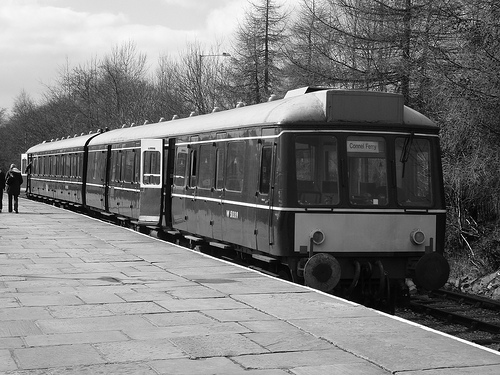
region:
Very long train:
[18, 86, 468, 297]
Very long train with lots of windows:
[15, 88, 465, 295]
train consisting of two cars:
[19, 77, 449, 300]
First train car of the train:
[84, 61, 463, 330]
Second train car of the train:
[16, 91, 99, 221]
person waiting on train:
[4, 148, 22, 219]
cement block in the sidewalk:
[171, 327, 266, 360]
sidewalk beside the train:
[0, 182, 497, 372]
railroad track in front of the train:
[374, 249, 496, 347]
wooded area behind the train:
[0, 59, 492, 133]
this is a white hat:
[6, 163, 23, 175]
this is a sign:
[337, 132, 384, 154]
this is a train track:
[396, 260, 498, 355]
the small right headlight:
[307, 225, 332, 244]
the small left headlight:
[396, 216, 443, 256]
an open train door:
[137, 120, 166, 233]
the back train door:
[12, 151, 38, 196]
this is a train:
[15, 96, 446, 314]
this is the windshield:
[283, 123, 444, 216]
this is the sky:
[15, 69, 50, 98]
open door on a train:
[139, 129, 163, 228]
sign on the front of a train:
[336, 130, 386, 164]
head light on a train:
[307, 221, 332, 248]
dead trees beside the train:
[65, 58, 225, 110]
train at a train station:
[10, 75, 472, 307]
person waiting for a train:
[4, 156, 29, 221]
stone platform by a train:
[14, 219, 181, 364]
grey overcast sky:
[14, 46, 53, 77]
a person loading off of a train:
[22, 143, 39, 188]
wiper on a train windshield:
[398, 104, 420, 181]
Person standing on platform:
[3, 148, 84, 235]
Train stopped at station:
[18, 104, 457, 296]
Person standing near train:
[2, 103, 362, 283]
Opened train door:
[129, 114, 199, 244]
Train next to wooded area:
[29, 34, 491, 317]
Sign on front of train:
[291, 89, 442, 281]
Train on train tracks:
[274, 57, 496, 349]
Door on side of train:
[131, 133, 163, 226]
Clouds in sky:
[22, 6, 247, 46]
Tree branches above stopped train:
[290, 8, 460, 309]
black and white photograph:
[6, 0, 499, 368]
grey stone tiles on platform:
[2, 197, 495, 372]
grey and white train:
[10, 74, 467, 303]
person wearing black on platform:
[1, 160, 25, 215]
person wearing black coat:
[3, 160, 31, 216]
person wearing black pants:
[5, 158, 24, 218]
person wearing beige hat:
[7, 162, 25, 212]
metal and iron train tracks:
[381, 279, 497, 363]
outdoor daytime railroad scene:
[1, 0, 486, 367]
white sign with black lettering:
[344, 137, 384, 157]